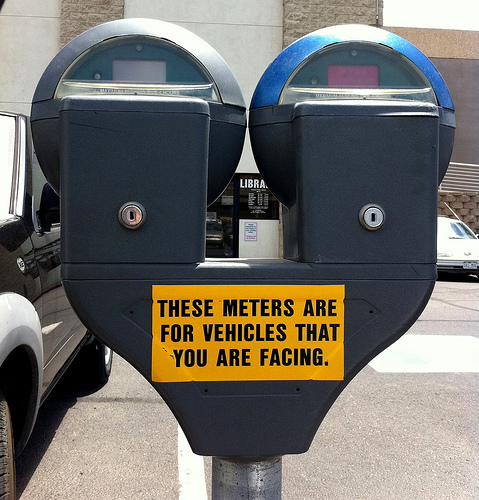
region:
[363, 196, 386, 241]
silver and white bolt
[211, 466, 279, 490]
black spots on gray post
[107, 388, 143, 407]
lines on the sidewalk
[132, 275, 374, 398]
yellow color on the parking meter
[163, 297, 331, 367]
black wording on the sign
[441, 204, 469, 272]
section of white car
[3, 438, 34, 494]
black wheel on car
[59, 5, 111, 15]
gray stone wall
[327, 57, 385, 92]
purple color in the parking meter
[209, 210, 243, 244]
clear windows in front of the building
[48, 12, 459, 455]
two gray parking meters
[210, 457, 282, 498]
silver pole parking meters are on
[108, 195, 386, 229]
key holes on the back of parking meters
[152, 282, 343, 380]
yellow sticker on back of parking meters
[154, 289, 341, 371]
black lettering on yellow background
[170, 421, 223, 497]
white lines painted on the pavement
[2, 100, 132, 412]
black suv in the parking lot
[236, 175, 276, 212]
white littering on black background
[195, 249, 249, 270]
square of sunlight on parking meter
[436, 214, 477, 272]
silver car in the parking lot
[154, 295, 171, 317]
the black letter T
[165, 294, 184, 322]
the black letter H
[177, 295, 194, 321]
the black letter E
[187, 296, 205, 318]
the black letter S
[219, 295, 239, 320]
the black letter M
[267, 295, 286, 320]
the black letter R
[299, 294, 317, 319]
the black letter A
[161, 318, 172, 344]
the black letter F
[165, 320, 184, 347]
the black letter O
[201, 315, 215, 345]
the black letter V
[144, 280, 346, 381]
Yellow and black sticker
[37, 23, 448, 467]
The meter is black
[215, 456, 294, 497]
The meter is attached to a grey pole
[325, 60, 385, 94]
Violet screen on the meter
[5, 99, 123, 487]
The vehicle is black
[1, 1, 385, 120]
The building has tan brick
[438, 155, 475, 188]
The rails on the fence are tan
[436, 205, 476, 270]
The car is white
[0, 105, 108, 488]
The vehicle is parked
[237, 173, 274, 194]
White letters on black window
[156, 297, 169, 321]
a T on a sign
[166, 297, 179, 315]
an H on a sign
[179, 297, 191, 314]
the E on a sign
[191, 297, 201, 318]
the S on a sign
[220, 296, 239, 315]
the M on a sign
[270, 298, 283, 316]
the R on a sign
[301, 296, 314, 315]
the A on a sign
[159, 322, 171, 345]
the F on a sign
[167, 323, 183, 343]
the O on a sign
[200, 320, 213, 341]
the V on a sign